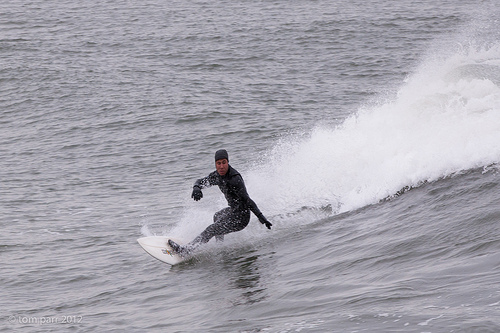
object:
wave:
[436, 236, 499, 260]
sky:
[401, 206, 418, 217]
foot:
[167, 238, 186, 252]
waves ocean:
[355, 99, 463, 196]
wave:
[442, 180, 499, 228]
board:
[137, 232, 230, 266]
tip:
[137, 237, 146, 248]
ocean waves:
[90, 46, 498, 140]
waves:
[323, 85, 447, 190]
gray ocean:
[308, 40, 436, 148]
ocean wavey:
[400, 127, 498, 222]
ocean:
[2, 0, 499, 331]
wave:
[7, 303, 76, 315]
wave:
[61, 270, 101, 283]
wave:
[53, 122, 98, 132]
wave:
[340, 58, 382, 65]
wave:
[178, 32, 227, 42]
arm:
[233, 176, 267, 224]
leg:
[179, 205, 241, 260]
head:
[214, 150, 231, 176]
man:
[163, 148, 272, 253]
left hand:
[263, 220, 272, 230]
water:
[248, 12, 493, 205]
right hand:
[188, 185, 207, 201]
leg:
[212, 208, 228, 244]